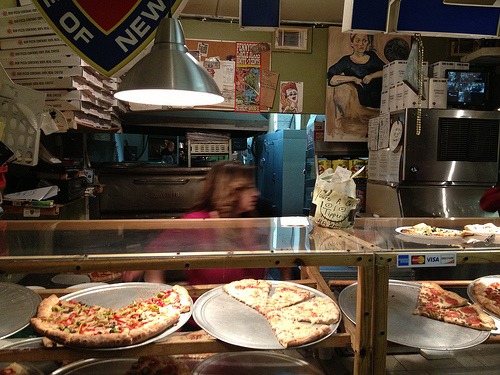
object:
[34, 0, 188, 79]
sign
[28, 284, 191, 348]
pizza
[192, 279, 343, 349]
pan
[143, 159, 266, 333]
woman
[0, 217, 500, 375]
counter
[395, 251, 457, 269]
logos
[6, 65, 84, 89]
boxes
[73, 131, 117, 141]
shelf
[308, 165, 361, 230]
bag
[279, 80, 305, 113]
painting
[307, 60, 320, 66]
wall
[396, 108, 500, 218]
stove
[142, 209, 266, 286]
shirt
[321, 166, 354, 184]
trash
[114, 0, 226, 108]
light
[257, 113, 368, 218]
kitchen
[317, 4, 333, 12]
ceiling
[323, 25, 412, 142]
picture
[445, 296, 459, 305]
pepperoni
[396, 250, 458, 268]
sticker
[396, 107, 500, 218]
oven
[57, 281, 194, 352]
tray